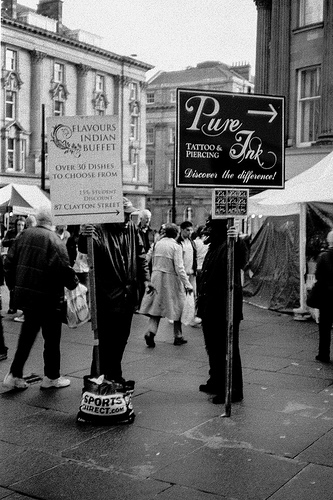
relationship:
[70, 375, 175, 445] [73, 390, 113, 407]
bag has writing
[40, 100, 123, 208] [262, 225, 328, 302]
sign for buffet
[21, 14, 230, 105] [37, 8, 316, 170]
buildings in background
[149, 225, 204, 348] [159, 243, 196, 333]
person in coat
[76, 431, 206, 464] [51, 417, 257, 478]
tiles on ground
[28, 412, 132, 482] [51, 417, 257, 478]
cement on ground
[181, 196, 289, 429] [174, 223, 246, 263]
man has mask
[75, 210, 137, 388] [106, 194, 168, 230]
person has cap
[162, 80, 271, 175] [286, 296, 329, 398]
sign for parlor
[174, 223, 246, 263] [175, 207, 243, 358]
mask of gorilla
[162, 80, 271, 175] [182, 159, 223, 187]
sign says imagine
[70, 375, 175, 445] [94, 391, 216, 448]
bag has ad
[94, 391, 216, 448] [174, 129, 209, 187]
ad for tattos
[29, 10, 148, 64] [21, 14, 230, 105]
top of buildings